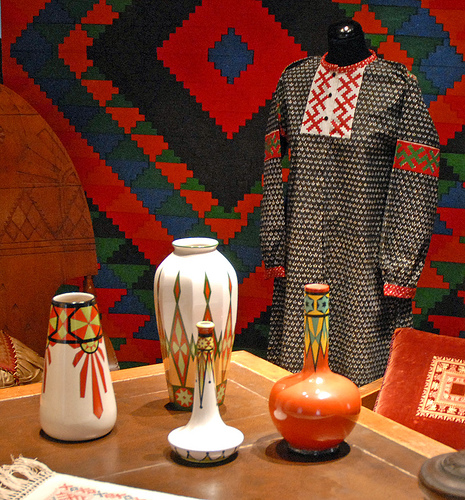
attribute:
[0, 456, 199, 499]
cloth — indian, white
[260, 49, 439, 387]
costume — traditional, gray, indian, cloth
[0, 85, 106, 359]
chair — wooden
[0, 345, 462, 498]
line — yellow, brown, wooden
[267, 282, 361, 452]
glass — red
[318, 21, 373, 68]
mannequin — headless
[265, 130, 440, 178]
design — green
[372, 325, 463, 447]
pillow — orange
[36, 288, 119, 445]
vase — medium, yellow, angular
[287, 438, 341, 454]
base — bronze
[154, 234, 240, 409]
vase — large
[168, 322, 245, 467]
vase — small, odd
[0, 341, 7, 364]
design — brown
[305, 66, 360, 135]
line — black, pink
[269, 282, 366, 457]
vase — indian, orange, small